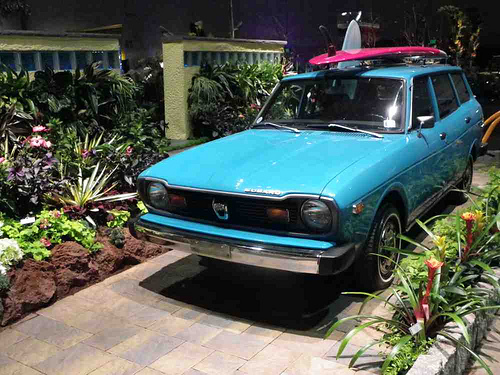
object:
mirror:
[413, 114, 435, 138]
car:
[125, 61, 491, 292]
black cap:
[316, 242, 356, 279]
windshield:
[252, 75, 408, 135]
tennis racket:
[185, 59, 236, 106]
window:
[410, 72, 437, 131]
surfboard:
[331, 9, 363, 100]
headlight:
[146, 180, 171, 210]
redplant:
[414, 259, 439, 327]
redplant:
[459, 204, 476, 259]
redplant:
[28, 123, 48, 134]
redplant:
[36, 236, 50, 246]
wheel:
[362, 205, 404, 292]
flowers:
[26, 132, 52, 148]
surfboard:
[306, 45, 451, 68]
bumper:
[133, 210, 339, 279]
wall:
[160, 42, 188, 141]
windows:
[429, 72, 462, 122]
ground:
[0, 152, 499, 374]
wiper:
[326, 122, 381, 139]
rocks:
[0, 256, 59, 328]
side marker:
[349, 201, 363, 215]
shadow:
[137, 250, 366, 341]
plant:
[39, 158, 141, 214]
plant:
[4, 123, 62, 211]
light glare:
[380, 82, 406, 130]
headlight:
[298, 197, 333, 235]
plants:
[188, 74, 225, 107]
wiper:
[253, 122, 299, 132]